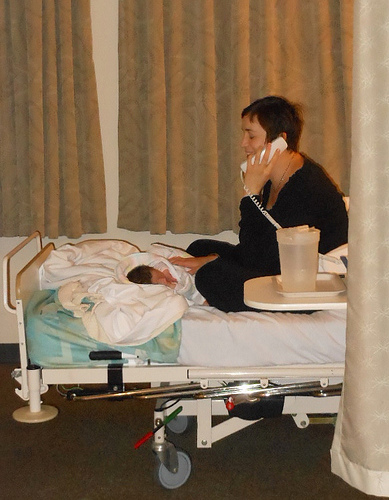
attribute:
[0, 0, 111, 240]
curtain — dark, tan, drawn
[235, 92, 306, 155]
hair — short, dark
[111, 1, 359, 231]
curtain — dark tan